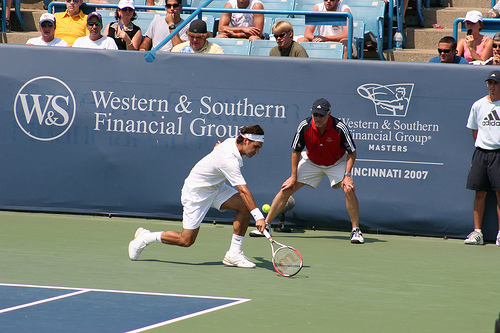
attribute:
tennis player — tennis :
[122, 118, 313, 284]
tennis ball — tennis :
[258, 198, 277, 221]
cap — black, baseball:
[304, 97, 336, 122]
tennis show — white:
[121, 226, 153, 261]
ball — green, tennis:
[261, 189, 276, 224]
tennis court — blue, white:
[2, 271, 252, 329]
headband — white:
[240, 129, 278, 150]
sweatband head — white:
[234, 122, 265, 159]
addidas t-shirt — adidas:
[460, 89, 496, 145]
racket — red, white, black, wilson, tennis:
[259, 223, 305, 278]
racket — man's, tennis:
[258, 220, 308, 286]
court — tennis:
[0, 204, 498, 331]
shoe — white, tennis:
[224, 248, 256, 268]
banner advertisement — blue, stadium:
[1, 43, 498, 240]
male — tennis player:
[127, 116, 302, 269]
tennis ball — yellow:
[259, 202, 274, 214]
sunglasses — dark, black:
[270, 31, 291, 39]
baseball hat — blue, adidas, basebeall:
[309, 94, 331, 115]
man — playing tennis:
[122, 116, 270, 271]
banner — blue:
[1, 39, 498, 238]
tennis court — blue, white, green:
[0, 209, 499, 329]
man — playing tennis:
[117, 115, 284, 272]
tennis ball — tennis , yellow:
[262, 202, 272, 213]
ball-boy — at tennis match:
[440, 57, 498, 260]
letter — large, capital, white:
[90, 87, 111, 112]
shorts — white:
[295, 152, 356, 187]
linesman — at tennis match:
[252, 97, 365, 242]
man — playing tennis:
[248, 97, 365, 244]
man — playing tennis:
[465, 70, 497, 244]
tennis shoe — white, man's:
[108, 229, 275, 291]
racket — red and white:
[257, 220, 306, 280]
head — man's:
[235, 123, 271, 155]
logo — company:
[15, 71, 83, 152]